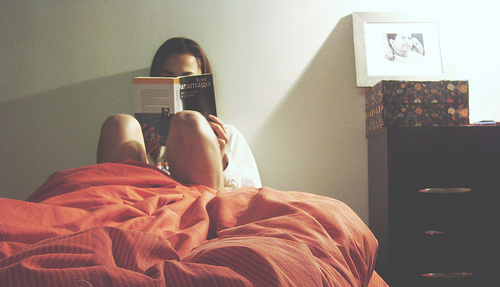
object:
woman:
[98, 36, 263, 187]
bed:
[0, 160, 389, 287]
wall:
[0, 0, 499, 224]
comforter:
[0, 159, 380, 287]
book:
[134, 74, 217, 146]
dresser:
[366, 124, 498, 286]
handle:
[418, 187, 471, 194]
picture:
[363, 21, 444, 78]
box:
[363, 79, 470, 134]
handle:
[421, 271, 476, 276]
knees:
[170, 109, 209, 126]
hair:
[148, 36, 211, 78]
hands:
[203, 113, 231, 161]